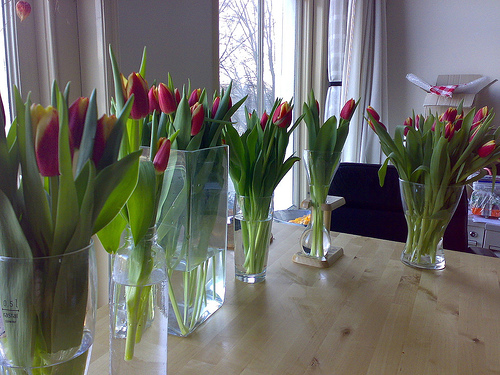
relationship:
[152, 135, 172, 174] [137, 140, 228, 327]
flowers in vase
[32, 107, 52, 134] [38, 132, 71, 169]
yellow center on pink tulip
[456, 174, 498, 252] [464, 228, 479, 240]
cabinet has lock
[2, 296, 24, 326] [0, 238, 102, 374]
measuring marker on vase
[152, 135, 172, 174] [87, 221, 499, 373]
flowers on table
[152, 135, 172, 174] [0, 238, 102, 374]
flowers in vase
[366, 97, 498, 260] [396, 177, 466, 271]
flowers in vase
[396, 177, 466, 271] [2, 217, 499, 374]
vase on table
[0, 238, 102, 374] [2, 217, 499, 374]
vase on table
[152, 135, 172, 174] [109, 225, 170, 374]
flowers in vase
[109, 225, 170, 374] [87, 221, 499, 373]
vase on table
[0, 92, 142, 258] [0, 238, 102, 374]
flowers in vase